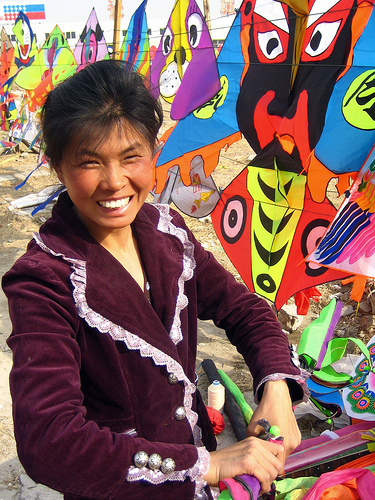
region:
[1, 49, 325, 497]
Woman is smiling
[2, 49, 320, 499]
Woman wears a purple coat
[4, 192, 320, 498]
Coat has white and purple embroidery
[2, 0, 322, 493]
Woman is folding a kite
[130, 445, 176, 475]
Tree buttons on sleeve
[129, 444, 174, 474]
Buttons on sleeve are grey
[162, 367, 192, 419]
Two front buttons buttoning the coat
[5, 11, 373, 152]
Colorful kits on left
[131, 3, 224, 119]
Kite with a shape of dog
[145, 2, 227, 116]
Kite is yellow and purple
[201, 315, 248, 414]
shadow is cast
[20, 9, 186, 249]
the woman has black hair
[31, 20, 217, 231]
the woman is smiling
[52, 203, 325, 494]
the woman is holding a kite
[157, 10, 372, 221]
kites are hanged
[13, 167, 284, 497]
the woman has a maroon coat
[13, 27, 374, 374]
it is sunny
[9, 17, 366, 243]
different kind of kites are there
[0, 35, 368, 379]
it is a daytime scene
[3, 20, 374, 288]
it is an outdoor scene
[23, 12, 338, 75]
kites are tied to the rope.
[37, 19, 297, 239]
lady is selling the kite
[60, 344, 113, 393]
lady is wearing purple color dress.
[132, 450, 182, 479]
silver color buttons are in coat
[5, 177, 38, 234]
shadows are in ground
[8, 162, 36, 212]
brown color sand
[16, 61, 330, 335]
daytime picture.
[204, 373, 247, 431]
brown color bottle is in ground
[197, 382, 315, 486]
lady is folding the kite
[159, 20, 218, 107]
dog face kite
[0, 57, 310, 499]
woman is rolling a kite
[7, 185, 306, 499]
woman is wearing a purple blouse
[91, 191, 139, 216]
woman is smiling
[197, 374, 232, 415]
roll of twine on ground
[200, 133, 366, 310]
face on a kite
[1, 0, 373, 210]
row of kites hanging on a string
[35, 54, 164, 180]
woman's hair is black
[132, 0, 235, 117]
kite looks like a puppy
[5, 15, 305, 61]
building in the background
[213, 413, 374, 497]
rolled kite is in the woman's hands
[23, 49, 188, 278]
a lady with a big smile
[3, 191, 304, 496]
a purple jacket with lace trim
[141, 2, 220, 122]
an abstract face of a dog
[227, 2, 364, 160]
artistic view of evil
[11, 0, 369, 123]
a colorful mural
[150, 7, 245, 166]
a kite of blue, yellow and purple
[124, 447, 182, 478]
three buttons on a sleeve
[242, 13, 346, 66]
slanted black eyes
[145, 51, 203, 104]
an illustration of dog whispers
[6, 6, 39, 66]
a cyclops with big lips